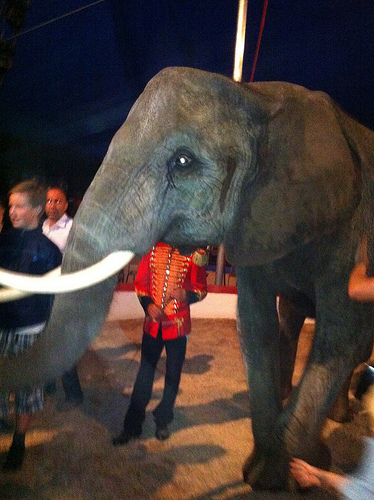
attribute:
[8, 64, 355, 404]
elephant — gray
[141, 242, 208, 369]
uniform — red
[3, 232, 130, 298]
tusks — ivory, white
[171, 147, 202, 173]
eye — open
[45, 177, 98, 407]
man — standing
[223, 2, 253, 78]
pole — metal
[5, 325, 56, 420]
shorts — plaid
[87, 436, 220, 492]
dirt — in the arena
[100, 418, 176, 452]
shoes — blurry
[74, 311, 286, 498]
ground — brown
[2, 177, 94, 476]
boy — smiling